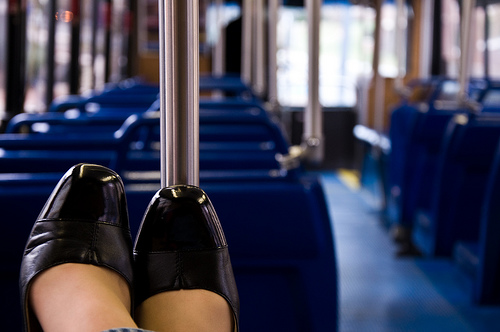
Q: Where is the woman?
A: On a bus.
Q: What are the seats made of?
A: Plastic.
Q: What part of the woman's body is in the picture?
A: Feet.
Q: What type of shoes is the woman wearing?
A: Flats.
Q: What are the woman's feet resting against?
A: A metal pole.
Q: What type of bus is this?
A: A city bus.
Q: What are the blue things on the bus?
A: Seats.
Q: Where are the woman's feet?
A: On the seat.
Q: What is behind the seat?
A: Pole.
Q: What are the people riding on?
A: Bus.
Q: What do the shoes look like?
A: Black.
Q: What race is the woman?
A: White.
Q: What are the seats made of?
A: Plastic.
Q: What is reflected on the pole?
A: Light.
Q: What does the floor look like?
A: Blue.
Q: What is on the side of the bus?
A: Windows.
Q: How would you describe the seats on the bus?
A: Blue.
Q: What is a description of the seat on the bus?
A: It is blue.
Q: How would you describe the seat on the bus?
A: Blue.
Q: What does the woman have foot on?
A: The blue seat on the bus.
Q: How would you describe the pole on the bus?
A: Tall and silver.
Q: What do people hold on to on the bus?
A: A tall silver pole.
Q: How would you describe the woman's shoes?
A: Black.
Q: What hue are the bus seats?
A: Blue.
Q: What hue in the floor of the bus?
A: Blue.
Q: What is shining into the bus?
A: The sun.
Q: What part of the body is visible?
A: Feet.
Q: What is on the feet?
A: Shoes.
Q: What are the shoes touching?
A: A metal pole.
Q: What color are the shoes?
A: Black.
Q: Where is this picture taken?
A: On a public bus.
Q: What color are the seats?
A: Blue.